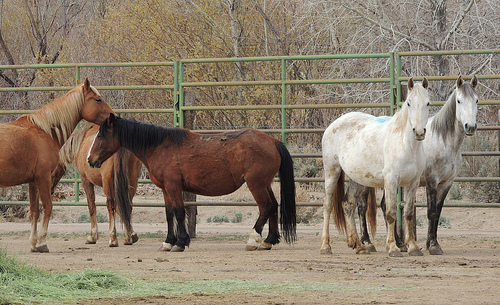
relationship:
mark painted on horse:
[371, 115, 391, 123] [315, 76, 432, 258]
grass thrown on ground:
[0, 245, 420, 303] [1, 220, 484, 302]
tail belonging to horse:
[272, 137, 296, 247] [83, 111, 299, 253]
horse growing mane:
[83, 111, 299, 253] [96, 112, 188, 153]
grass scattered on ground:
[0, 242, 421, 304] [1, 220, 484, 302]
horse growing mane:
[0, 76, 115, 251] [15, 80, 85, 146]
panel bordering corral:
[0, 58, 178, 208] [1, 218, 484, 303]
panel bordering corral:
[177, 50, 402, 243] [1, 218, 484, 303]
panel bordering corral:
[395, 46, 485, 243] [1, 218, 484, 303]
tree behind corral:
[283, 0, 498, 144] [0, 57, 498, 304]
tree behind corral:
[338, 0, 488, 205] [0, 57, 498, 304]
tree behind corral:
[0, 0, 85, 116] [0, 57, 498, 304]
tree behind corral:
[22, 0, 72, 141] [0, 57, 498, 304]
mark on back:
[377, 114, 390, 124] [320, 102, 405, 128]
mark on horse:
[377, 114, 390, 124] [315, 76, 432, 258]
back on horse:
[320, 102, 405, 128] [315, 76, 432, 258]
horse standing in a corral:
[426, 74, 481, 265] [0, 57, 498, 304]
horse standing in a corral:
[315, 76, 432, 258] [0, 57, 498, 304]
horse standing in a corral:
[83, 111, 299, 253] [0, 57, 498, 304]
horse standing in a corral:
[68, 119, 137, 242] [0, 57, 498, 304]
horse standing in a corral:
[0, 76, 115, 251] [0, 57, 498, 304]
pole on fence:
[179, 104, 285, 112] [6, 51, 497, 229]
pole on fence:
[291, 54, 400, 63] [6, 51, 497, 229]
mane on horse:
[17, 81, 109, 150] [0, 76, 115, 251]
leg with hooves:
[163, 181, 191, 245] [152, 240, 177, 257]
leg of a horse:
[163, 181, 191, 245] [83, 111, 299, 253]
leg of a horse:
[163, 181, 191, 245] [92, 117, 293, 257]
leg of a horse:
[157, 190, 186, 250] [111, 103, 294, 254]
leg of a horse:
[163, 181, 191, 245] [78, 104, 295, 243]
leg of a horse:
[317, 177, 335, 263] [296, 69, 439, 236]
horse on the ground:
[315, 78, 440, 261] [305, 264, 358, 286]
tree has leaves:
[283, 0, 498, 144] [162, 23, 185, 50]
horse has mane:
[81, 106, 304, 256] [112, 115, 190, 156]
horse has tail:
[83, 111, 299, 253] [273, 139, 302, 246]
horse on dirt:
[315, 76, 432, 258] [2, 231, 483, 302]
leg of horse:
[317, 163, 342, 257] [315, 76, 432, 258]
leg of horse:
[317, 163, 342, 257] [315, 78, 440, 261]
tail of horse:
[272, 131, 306, 240] [82, 120, 300, 249]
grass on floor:
[0, 242, 421, 304] [0, 197, 499, 304]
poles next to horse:
[181, 51, 393, 191] [6, 65, 482, 252]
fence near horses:
[4, 56, 493, 243] [1, 69, 482, 261]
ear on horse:
[402, 74, 414, 90] [315, 78, 440, 261]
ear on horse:
[415, 69, 429, 90] [315, 78, 440, 261]